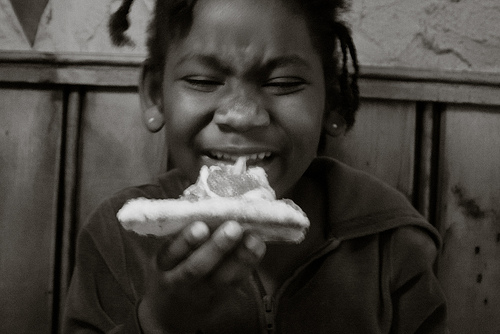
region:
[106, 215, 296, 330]
girls hand is black in small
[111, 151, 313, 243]
piece of pepperoni pizza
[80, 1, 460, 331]
Child eating a slice of pizza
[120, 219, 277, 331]
A child's hand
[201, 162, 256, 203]
slice of pepperoni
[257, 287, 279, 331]
Zipper pull tab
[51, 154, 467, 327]
A child's sweatshirt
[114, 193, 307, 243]
pizza crust on a slice of pizza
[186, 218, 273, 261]
A child's fingernails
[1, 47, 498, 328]
Wooden paneled wall in background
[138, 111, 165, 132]
The child's left ear ring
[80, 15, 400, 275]
child showing deep emotion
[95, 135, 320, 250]
pizza slice in front of mouth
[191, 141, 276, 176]
mouth open with teeth showing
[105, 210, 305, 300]
hand supporting the pizza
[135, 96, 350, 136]
small earrings in lobes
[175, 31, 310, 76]
puffiness above eyebrows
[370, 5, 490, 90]
stucco surface of wall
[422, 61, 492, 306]
marks on wood paneling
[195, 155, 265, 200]
pepperoni slice on pizza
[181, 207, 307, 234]
char on edge of crust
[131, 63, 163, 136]
The girl's left ear.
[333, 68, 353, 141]
The girl's right ear.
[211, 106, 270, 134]
The girl's nose and nostrils.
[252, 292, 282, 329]
The zipper on the girl's sweater.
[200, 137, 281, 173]
The girl's mouth.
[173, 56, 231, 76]
The girl's left eyebrow.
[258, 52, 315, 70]
The girl's right eyebrow.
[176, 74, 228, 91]
The girl's left eye.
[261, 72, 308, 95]
The girl's right eye.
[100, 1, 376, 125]
The girl's braids.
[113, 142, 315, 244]
slice of pizza endorses animal cruelty